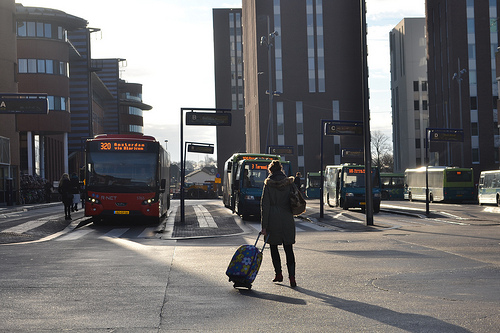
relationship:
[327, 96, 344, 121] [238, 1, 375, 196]
window in building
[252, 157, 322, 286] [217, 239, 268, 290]
woman holding suitcase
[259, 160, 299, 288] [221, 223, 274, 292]
woman walking with floral suitcase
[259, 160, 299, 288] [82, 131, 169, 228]
woman waiting for bus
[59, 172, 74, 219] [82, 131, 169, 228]
passenger waiting for bus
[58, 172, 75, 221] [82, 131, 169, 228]
passenger getting onto bus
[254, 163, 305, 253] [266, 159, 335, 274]
coat on woman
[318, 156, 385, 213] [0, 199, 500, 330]
blue bus on road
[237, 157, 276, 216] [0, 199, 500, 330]
blue bus on road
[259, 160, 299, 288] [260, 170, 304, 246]
woman in coat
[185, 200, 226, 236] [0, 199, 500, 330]
lines on road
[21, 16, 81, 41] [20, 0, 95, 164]
windows in building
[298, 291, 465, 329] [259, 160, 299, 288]
shadow of woman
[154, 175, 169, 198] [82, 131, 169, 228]
side mirror of bus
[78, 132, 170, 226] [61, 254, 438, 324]
bus on paved road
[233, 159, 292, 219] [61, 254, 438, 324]
blue bus on paved road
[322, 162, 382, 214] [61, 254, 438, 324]
blue bus on paved road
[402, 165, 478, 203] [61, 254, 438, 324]
bus on paved road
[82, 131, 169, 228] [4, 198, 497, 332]
bus on road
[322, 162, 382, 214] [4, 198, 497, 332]
blue bus on road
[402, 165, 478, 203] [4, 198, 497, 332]
bus on road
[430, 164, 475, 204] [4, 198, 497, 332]
bus on road